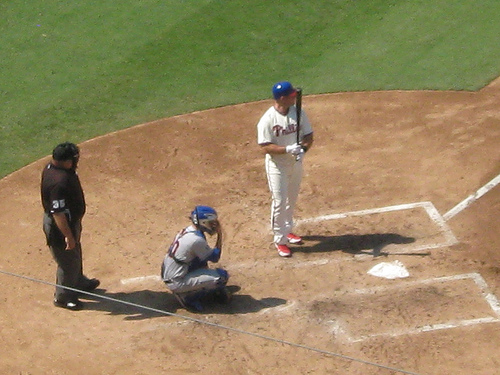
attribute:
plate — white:
[367, 260, 412, 284]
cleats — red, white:
[267, 217, 314, 268]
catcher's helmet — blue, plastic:
[190, 206, 221, 236]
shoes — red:
[271, 226, 306, 262]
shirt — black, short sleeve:
[40, 164, 86, 221]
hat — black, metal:
[268, 81, 302, 116]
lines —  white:
[270, 198, 498, 344]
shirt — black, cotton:
[30, 158, 104, 230]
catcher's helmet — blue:
[188, 203, 221, 236]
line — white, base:
[439, 171, 499, 223]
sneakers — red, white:
[273, 232, 310, 259]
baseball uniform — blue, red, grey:
[157, 221, 232, 302]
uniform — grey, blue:
[159, 205, 229, 309]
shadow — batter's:
[296, 227, 416, 266]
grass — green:
[3, 2, 497, 172]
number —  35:
[51, 199, 66, 211]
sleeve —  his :
[46, 184, 68, 211]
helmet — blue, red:
[270, 79, 299, 103]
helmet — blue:
[271, 78, 299, 99]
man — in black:
[39, 138, 100, 310]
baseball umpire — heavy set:
[36, 142, 101, 311]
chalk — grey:
[270, 202, 497, 348]